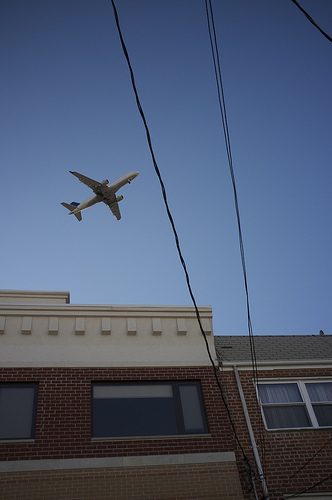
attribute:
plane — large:
[59, 169, 140, 223]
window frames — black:
[0, 371, 221, 443]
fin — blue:
[56, 199, 87, 225]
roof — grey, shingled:
[210, 321, 331, 370]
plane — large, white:
[50, 156, 142, 237]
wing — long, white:
[64, 167, 108, 191]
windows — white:
[255, 380, 306, 433]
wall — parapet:
[1, 368, 227, 498]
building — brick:
[1, 337, 233, 494]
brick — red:
[47, 411, 81, 454]